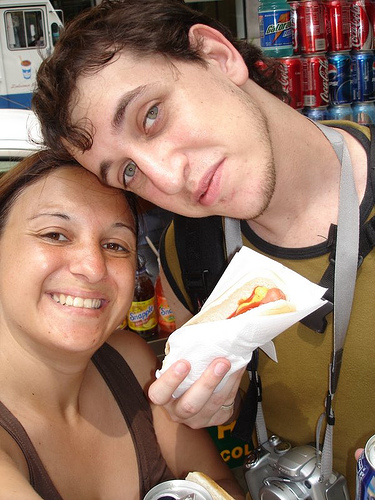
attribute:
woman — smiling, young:
[4, 145, 237, 499]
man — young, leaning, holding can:
[38, 4, 375, 489]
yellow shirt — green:
[167, 119, 374, 488]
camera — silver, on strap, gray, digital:
[241, 434, 350, 498]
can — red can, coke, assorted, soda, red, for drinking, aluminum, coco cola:
[244, 0, 374, 118]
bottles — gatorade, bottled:
[255, 3, 292, 58]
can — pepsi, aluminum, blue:
[329, 54, 374, 102]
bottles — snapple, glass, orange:
[129, 249, 181, 338]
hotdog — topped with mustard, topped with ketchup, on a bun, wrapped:
[160, 289, 299, 382]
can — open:
[136, 475, 228, 499]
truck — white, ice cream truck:
[3, 7, 75, 168]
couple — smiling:
[0, 13, 374, 499]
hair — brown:
[0, 141, 81, 209]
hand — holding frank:
[148, 359, 255, 433]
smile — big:
[44, 288, 112, 317]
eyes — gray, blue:
[124, 96, 177, 186]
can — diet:
[304, 104, 374, 130]